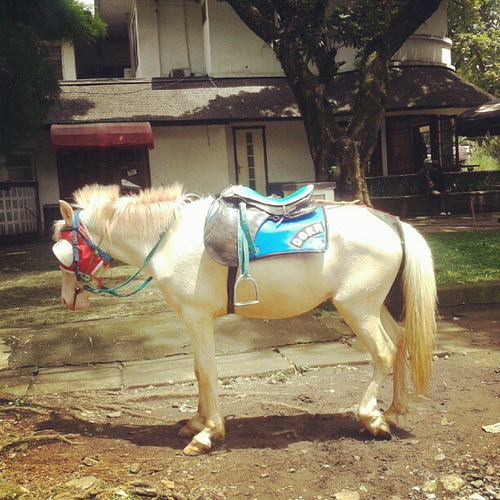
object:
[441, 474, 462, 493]
rock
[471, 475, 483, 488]
rock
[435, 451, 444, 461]
rock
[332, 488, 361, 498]
rock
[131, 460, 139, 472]
rock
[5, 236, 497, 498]
ground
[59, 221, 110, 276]
material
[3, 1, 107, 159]
tree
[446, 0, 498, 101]
tree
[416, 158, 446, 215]
man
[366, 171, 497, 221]
bench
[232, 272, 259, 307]
stirrup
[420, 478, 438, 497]
rock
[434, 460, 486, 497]
rock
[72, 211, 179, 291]
rein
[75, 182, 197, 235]
mane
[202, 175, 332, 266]
saddle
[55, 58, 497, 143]
roof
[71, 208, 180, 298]
harness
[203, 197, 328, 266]
blanket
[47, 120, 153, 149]
awning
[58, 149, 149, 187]
entrance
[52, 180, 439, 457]
horse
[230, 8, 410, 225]
tree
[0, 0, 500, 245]
building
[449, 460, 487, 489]
rock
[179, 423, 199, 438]
hoof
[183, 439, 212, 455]
hoof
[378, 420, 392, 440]
hoof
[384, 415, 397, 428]
hoof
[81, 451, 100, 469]
road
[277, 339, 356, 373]
rocks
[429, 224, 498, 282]
grass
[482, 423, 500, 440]
rock